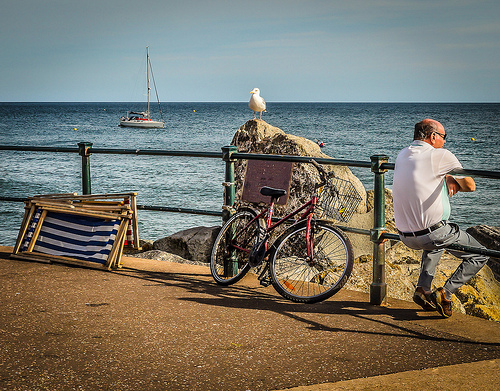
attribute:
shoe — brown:
[409, 283, 437, 313]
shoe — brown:
[427, 284, 454, 319]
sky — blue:
[306, 22, 373, 52]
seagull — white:
[232, 84, 277, 119]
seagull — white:
[241, 82, 271, 127]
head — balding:
[410, 112, 447, 149]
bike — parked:
[158, 149, 398, 331]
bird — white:
[247, 85, 267, 122]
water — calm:
[307, 85, 412, 158]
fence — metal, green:
[2, 140, 494, 312]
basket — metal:
[319, 173, 363, 224]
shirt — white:
[391, 139, 461, 233]